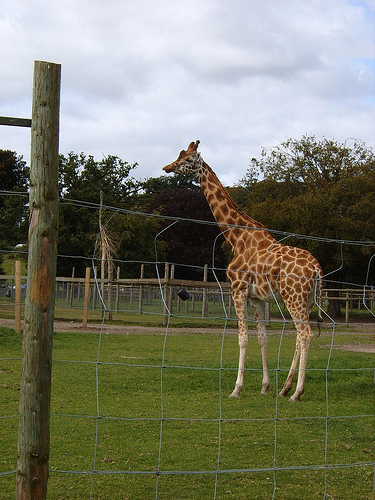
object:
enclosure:
[0, 50, 375, 499]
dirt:
[1, 310, 347, 338]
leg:
[288, 311, 315, 403]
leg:
[276, 332, 299, 397]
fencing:
[199, 260, 210, 321]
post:
[12, 47, 67, 497]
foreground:
[0, 298, 375, 498]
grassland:
[0, 320, 371, 498]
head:
[160, 140, 203, 181]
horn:
[187, 141, 195, 148]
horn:
[194, 139, 201, 151]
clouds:
[2, 1, 373, 189]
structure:
[5, 211, 375, 345]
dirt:
[0, 366, 375, 461]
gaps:
[95, 361, 162, 422]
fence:
[6, 189, 374, 498]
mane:
[195, 155, 266, 234]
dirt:
[57, 325, 68, 331]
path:
[50, 318, 366, 337]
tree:
[237, 129, 374, 184]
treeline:
[2, 151, 370, 279]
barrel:
[176, 286, 190, 302]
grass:
[151, 335, 224, 404]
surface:
[0, 292, 375, 498]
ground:
[1, 296, 373, 499]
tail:
[312, 260, 324, 340]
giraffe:
[162, 138, 324, 401]